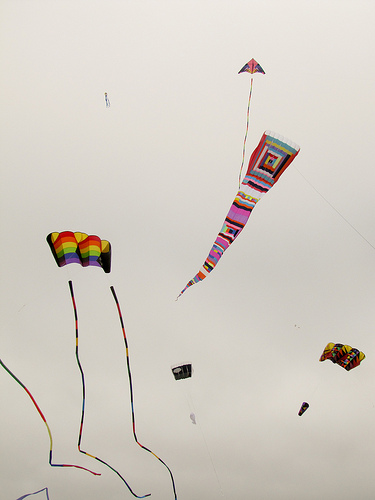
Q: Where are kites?
A: In the sky.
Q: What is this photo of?
A: Flying kites.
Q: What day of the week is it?
A: Tuesday.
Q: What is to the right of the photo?
A: A psychedelic kite.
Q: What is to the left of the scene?
A: A kite with very long tails.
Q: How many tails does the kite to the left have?
A: 2.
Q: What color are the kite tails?
A: Rainbow striped.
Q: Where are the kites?
A: Flying in the sky.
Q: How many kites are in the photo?
A: 5.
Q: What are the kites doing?
A: Flying.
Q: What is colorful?
A: The kite.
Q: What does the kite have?
A: A long tail.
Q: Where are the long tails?
A: On a kite.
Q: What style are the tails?
A: Skinny.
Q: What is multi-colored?
A: The tails.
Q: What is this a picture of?
A: Kites.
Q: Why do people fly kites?
A: For fun.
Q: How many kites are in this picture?
A: Five.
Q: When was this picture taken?
A: During the day.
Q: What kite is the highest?
A: The top right kite.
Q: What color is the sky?
A: Gray.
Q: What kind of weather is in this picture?
A: Cloudy.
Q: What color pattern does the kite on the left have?
A: Rainbow.